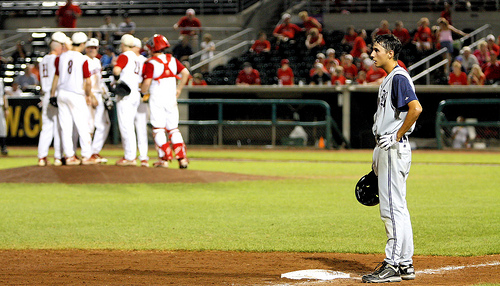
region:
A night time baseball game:
[2, 0, 489, 281]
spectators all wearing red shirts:
[262, 22, 371, 75]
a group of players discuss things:
[40, 27, 200, 164]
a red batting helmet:
[152, 35, 171, 52]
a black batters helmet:
[343, 160, 383, 212]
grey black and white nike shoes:
[364, 261, 412, 283]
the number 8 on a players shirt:
[57, 55, 84, 85]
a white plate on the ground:
[244, 252, 349, 284]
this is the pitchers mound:
[3, 154, 294, 198]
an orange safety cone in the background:
[312, 131, 334, 147]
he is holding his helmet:
[352, 162, 390, 213]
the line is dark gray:
[383, 175, 395, 208]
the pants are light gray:
[380, 159, 402, 195]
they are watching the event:
[316, 52, 371, 82]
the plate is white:
[283, 258, 339, 284]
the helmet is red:
[146, 32, 173, 51]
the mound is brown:
[98, 161, 122, 181]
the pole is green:
[238, 95, 268, 107]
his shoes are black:
[363, 259, 400, 284]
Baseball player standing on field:
[375, 37, 442, 262]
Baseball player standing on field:
[144, 37, 186, 158]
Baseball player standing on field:
[116, 34, 142, 149]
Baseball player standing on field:
[90, 30, 109, 127]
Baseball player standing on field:
[65, 38, 88, 142]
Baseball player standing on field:
[42, 13, 53, 149]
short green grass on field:
[141, 187, 241, 242]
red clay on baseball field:
[142, 226, 234, 271]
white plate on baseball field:
[268, 240, 353, 284]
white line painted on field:
[449, 251, 483, 283]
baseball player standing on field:
[352, 8, 413, 284]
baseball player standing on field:
[152, 35, 192, 162]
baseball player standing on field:
[117, 18, 144, 142]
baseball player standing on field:
[88, 35, 107, 136]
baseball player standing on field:
[71, 37, 86, 151]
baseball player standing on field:
[34, 27, 54, 167]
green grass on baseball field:
[176, 169, 330, 263]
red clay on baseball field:
[109, 250, 165, 285]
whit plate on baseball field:
[266, 235, 342, 283]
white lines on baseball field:
[412, 248, 483, 282]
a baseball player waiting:
[353, 36, 430, 283]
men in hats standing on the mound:
[28, 30, 188, 173]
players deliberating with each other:
[35, 26, 190, 171]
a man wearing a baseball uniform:
[350, 35, 417, 281]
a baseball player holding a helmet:
[352, 32, 422, 277]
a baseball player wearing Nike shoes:
[355, 35, 421, 280]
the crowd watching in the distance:
[186, 16, 368, 146]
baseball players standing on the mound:
[30, 16, 190, 176]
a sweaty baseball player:
[356, 34, 428, 284]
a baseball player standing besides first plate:
[266, 28, 421, 284]